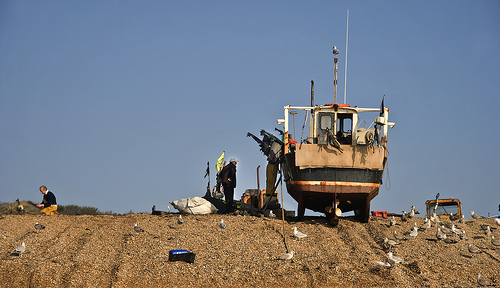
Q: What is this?
A: Bulldover.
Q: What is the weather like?
A: Sunny.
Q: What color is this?
A: Brown.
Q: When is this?
A: Daytime.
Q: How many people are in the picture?
A: Two.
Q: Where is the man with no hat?
A: Left side.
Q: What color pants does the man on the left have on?
A: Yellow.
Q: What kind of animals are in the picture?
A: Birds.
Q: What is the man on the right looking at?
A: Old boat.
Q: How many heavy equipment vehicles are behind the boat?
A: Two.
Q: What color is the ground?
A: Brown.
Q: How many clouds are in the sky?
A: Zero.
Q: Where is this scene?
A: At the dump.